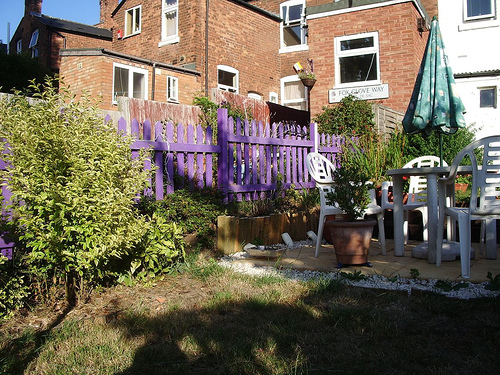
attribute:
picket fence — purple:
[0, 108, 361, 260]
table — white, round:
[387, 165, 482, 262]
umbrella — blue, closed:
[402, 15, 467, 167]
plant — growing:
[324, 163, 371, 221]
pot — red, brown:
[326, 217, 378, 265]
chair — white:
[307, 151, 387, 257]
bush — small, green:
[0, 72, 160, 301]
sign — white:
[328, 82, 390, 104]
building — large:
[0, 0, 438, 124]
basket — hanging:
[298, 60, 317, 88]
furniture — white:
[308, 134, 498, 279]